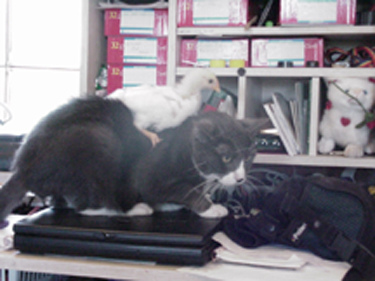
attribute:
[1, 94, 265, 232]
cat — black, white, gray, scared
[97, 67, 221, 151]
duck — orange, white, small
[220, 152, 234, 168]
eye — yellow, black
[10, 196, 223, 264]
laptop — black, thick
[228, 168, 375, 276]
backpack — black, blue, green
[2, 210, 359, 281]
table — messy, white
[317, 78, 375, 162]
bear — red, white, pink, stuffed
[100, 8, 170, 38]
boxes — red, white, pink white, blue, stacked, pink, multi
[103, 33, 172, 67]
boxes — red, white, stacked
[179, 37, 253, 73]
boxes — red, white, stacked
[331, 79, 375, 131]
rose — red, green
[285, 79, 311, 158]
papers — in nook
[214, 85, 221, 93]
beak — orange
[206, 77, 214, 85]
eye — black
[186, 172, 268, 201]
whiskers — long, white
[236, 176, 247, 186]
nose — white, black tipped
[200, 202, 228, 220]
feet — white